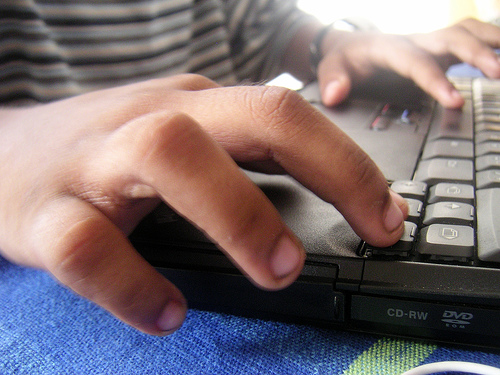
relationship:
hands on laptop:
[65, 59, 449, 371] [301, 9, 495, 286]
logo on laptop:
[442, 309, 472, 330] [119, 76, 496, 352]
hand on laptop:
[316, 17, 499, 109] [119, 76, 496, 352]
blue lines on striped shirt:
[64, 14, 121, 65] [3, 0, 323, 107]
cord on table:
[398, 357, 491, 373] [0, 277, 498, 370]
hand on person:
[317, 17, 500, 109] [1, 0, 499, 334]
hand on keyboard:
[317, 17, 500, 109] [348, 65, 498, 275]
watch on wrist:
[309, 12, 359, 70] [282, 16, 349, 84]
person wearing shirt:
[1, 0, 499, 334] [1, 0, 316, 109]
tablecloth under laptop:
[2, 261, 493, 373] [119, 76, 496, 352]